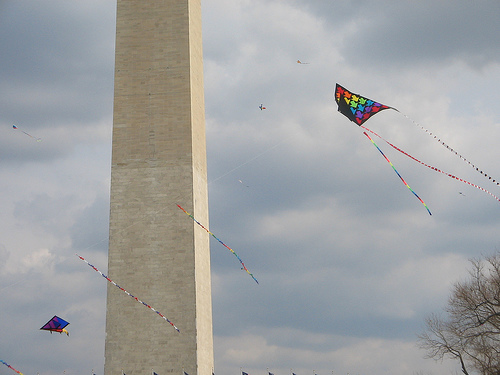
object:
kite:
[176, 204, 259, 284]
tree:
[408, 257, 500, 375]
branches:
[414, 248, 499, 373]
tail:
[170, 199, 267, 286]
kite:
[10, 121, 40, 143]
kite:
[333, 83, 500, 220]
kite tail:
[361, 124, 500, 215]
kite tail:
[64, 241, 188, 334]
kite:
[37, 313, 72, 340]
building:
[101, 0, 216, 375]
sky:
[2, 0, 498, 370]